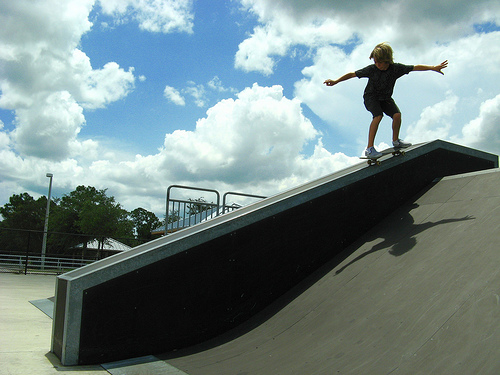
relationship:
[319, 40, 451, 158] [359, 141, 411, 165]
kid riding skateboard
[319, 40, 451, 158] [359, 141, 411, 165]
kid on skateboard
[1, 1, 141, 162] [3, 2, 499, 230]
clouds in sky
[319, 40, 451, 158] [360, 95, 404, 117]
kid wearing shorts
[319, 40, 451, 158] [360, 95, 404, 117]
kid in shorts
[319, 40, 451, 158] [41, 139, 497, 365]
kid on top of wall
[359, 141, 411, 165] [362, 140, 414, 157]
skateboard under feet